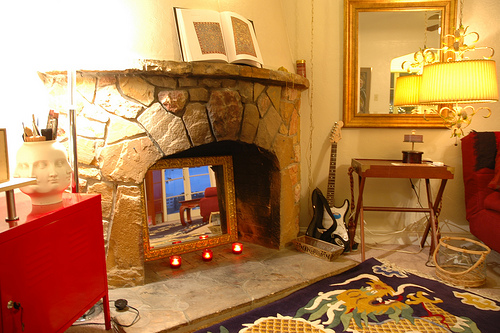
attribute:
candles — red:
[170, 233, 241, 274]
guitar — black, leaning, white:
[312, 118, 351, 255]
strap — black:
[310, 202, 339, 246]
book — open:
[158, 1, 262, 64]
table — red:
[0, 172, 103, 332]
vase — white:
[3, 133, 75, 207]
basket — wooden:
[442, 236, 487, 303]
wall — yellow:
[241, 6, 339, 47]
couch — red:
[461, 129, 500, 270]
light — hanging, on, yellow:
[405, 27, 499, 156]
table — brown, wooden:
[346, 137, 461, 275]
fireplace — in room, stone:
[137, 120, 293, 249]